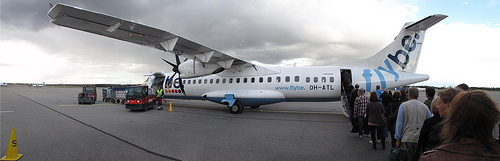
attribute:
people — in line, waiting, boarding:
[342, 70, 500, 161]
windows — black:
[177, 75, 340, 86]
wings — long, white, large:
[39, 2, 271, 70]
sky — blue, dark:
[2, 0, 500, 91]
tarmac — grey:
[4, 86, 500, 161]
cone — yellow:
[3, 124, 29, 159]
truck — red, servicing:
[123, 79, 167, 116]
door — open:
[337, 66, 363, 102]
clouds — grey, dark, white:
[1, 6, 315, 64]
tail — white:
[357, 11, 450, 103]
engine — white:
[159, 49, 220, 82]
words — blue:
[363, 23, 420, 93]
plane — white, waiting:
[48, 0, 448, 112]